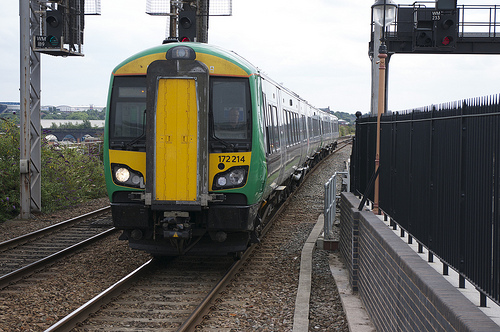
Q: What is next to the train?
A: A tall fence.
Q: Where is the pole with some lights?
A: Next to the train.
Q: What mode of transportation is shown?
A: Train.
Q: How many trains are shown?
A: 1.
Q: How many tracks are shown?
A: 2.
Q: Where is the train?
A: Tracks.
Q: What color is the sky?
A: Blue.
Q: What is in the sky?
A: Clouds.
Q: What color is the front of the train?
A: Yellow and green.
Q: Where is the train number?
A: Front of the train.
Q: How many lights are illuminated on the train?
A: 1.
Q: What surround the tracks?
A: Gravel.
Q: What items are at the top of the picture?
A: Signal lights.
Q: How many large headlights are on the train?
A: Two.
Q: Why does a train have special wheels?
A: To run on the track.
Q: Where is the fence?
A: On the platform.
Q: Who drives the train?
A: The conductor.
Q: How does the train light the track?
A: With headlights.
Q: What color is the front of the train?
A: Yellow.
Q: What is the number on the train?
A: 172214.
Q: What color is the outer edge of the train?
A: Green.